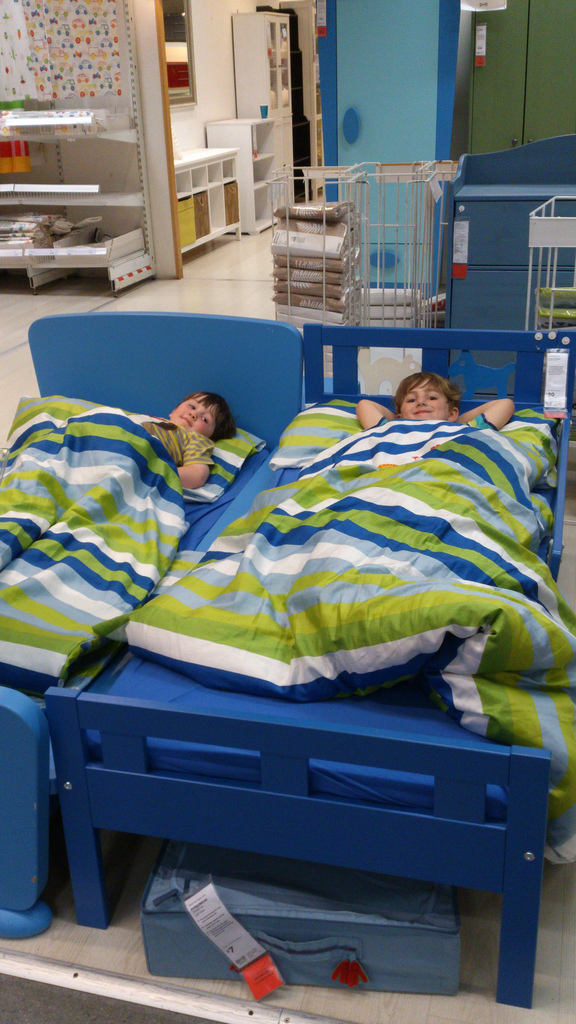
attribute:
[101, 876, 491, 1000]
suitcase — blue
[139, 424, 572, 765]
blanket — striped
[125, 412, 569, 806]
blanket — striped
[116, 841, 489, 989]
storage container — blue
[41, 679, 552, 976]
bed frame — blue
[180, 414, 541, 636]
stripes — wide, horizontal, green, white, blue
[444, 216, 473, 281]
label — long, white, orange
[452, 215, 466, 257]
printing — small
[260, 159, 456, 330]
racks — metallic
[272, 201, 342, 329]
linens — stacked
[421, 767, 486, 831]
wood — panel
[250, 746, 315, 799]
wood — panel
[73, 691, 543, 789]
wood — panel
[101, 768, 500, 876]
wood — panel